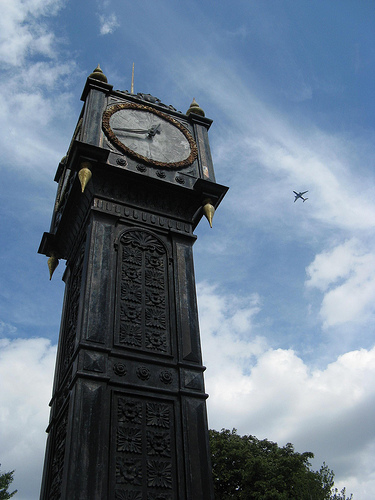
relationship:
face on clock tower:
[104, 94, 198, 179] [27, 63, 230, 493]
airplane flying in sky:
[288, 188, 313, 207] [215, 61, 352, 363]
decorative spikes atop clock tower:
[77, 163, 94, 194] [33, 53, 242, 498]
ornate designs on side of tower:
[96, 223, 195, 498] [37, 57, 230, 494]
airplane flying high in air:
[288, 188, 313, 207] [217, 62, 357, 331]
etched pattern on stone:
[106, 383, 189, 497] [97, 383, 197, 498]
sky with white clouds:
[233, 227, 372, 409] [264, 233, 372, 375]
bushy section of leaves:
[206, 425, 349, 497] [204, 418, 356, 498]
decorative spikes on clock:
[77, 163, 94, 194] [33, 71, 232, 498]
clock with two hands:
[99, 99, 199, 174] [106, 119, 168, 142]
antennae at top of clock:
[129, 64, 138, 98] [33, 71, 232, 498]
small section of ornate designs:
[101, 213, 189, 365] [111, 226, 170, 357]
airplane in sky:
[288, 188, 313, 207] [217, 83, 373, 316]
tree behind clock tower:
[208, 426, 356, 498] [33, 53, 242, 498]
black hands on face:
[112, 118, 165, 141] [104, 94, 206, 179]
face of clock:
[104, 94, 206, 179] [97, 98, 211, 181]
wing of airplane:
[297, 188, 310, 194] [290, 188, 313, 206]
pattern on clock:
[106, 223, 176, 360] [33, 71, 232, 498]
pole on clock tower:
[126, 58, 139, 93] [27, 63, 230, 493]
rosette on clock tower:
[110, 357, 132, 380] [27, 63, 230, 493]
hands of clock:
[111, 124, 167, 141] [99, 99, 199, 174]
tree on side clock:
[208, 426, 356, 498] [17, 61, 237, 498]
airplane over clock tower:
[288, 188, 313, 207] [27, 63, 230, 493]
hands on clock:
[150, 117, 167, 134] [99, 99, 199, 174]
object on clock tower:
[201, 201, 219, 229] [27, 63, 230, 493]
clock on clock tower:
[99, 99, 199, 174] [27, 63, 230, 493]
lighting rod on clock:
[127, 51, 138, 96] [33, 71, 232, 498]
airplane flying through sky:
[288, 188, 313, 207] [2, 2, 362, 499]